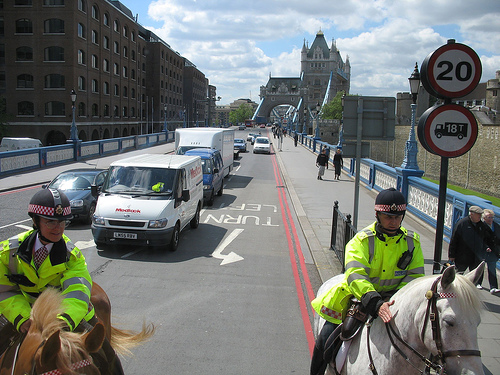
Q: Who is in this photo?
A: A policeman and a policewoman.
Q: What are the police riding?
A: Horses.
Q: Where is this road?
A: In Europe.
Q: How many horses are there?
A: Two.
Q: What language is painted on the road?
A: English.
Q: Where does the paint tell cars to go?
A: Left.